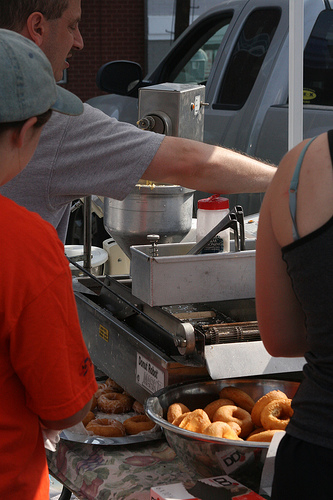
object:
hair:
[0, 0, 68, 32]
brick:
[110, 37, 120, 42]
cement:
[112, 27, 126, 28]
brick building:
[63, 5, 150, 86]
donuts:
[197, 422, 239, 442]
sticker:
[290, 91, 314, 101]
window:
[282, 6, 331, 105]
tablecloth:
[46, 443, 227, 499]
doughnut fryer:
[84, 194, 253, 379]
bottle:
[194, 189, 235, 253]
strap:
[287, 135, 321, 239]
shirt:
[0, 196, 103, 500]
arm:
[78, 116, 275, 203]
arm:
[246, 195, 310, 362]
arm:
[18, 328, 91, 433]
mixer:
[126, 87, 214, 143]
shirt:
[0, 97, 154, 233]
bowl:
[147, 379, 301, 484]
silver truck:
[94, 0, 331, 160]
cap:
[2, 26, 90, 125]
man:
[0, 2, 280, 212]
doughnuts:
[214, 404, 250, 423]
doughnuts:
[125, 416, 153, 434]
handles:
[185, 203, 247, 251]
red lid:
[194, 190, 230, 208]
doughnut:
[261, 398, 290, 426]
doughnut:
[96, 391, 131, 412]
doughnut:
[84, 415, 123, 436]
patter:
[111, 435, 166, 483]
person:
[0, 30, 100, 500]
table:
[46, 369, 298, 500]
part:
[86, 7, 136, 59]